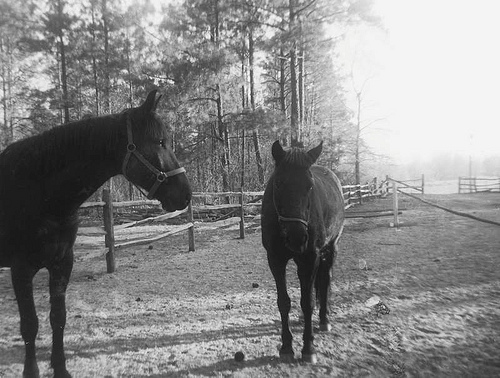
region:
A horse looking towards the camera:
[247, 135, 352, 366]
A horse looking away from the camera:
[0, 85, 190, 375]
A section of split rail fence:
[346, 172, 388, 241]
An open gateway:
[414, 170, 469, 199]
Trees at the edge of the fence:
[165, 31, 353, 143]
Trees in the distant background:
[378, 147, 498, 174]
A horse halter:
[116, 133, 186, 199]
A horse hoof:
[299, 348, 317, 365]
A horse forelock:
[281, 146, 311, 170]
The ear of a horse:
[308, 138, 327, 168]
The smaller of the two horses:
[247, 135, 347, 363]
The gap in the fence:
[419, 173, 463, 195]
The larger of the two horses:
[0, 84, 192, 376]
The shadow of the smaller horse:
[10, 303, 322, 377]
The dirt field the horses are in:
[2, 193, 499, 376]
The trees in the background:
[0, 1, 383, 227]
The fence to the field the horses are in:
[54, 170, 499, 276]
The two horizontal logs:
[390, 176, 499, 225]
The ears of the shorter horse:
[265, 133, 327, 165]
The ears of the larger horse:
[142, 86, 164, 114]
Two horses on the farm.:
[1, 111, 383, 316]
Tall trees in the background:
[148, 25, 299, 175]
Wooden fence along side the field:
[112, 194, 261, 247]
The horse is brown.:
[249, 141, 378, 362]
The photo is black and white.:
[45, 43, 499, 305]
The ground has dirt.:
[118, 284, 248, 366]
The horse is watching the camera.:
[263, 141, 355, 338]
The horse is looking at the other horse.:
[16, 94, 192, 335]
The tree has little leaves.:
[186, 13, 312, 157]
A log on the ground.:
[405, 204, 499, 234]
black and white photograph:
[37, 43, 469, 352]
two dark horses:
[20, 102, 387, 359]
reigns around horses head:
[117, 110, 204, 202]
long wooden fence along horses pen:
[98, 173, 295, 268]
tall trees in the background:
[187, 1, 309, 209]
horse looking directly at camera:
[274, 118, 345, 358]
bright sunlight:
[394, 18, 479, 158]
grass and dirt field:
[144, 246, 259, 358]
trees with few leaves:
[200, 0, 277, 196]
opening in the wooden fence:
[385, 166, 476, 200]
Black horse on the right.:
[246, 129, 353, 372]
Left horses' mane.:
[2, 98, 173, 175]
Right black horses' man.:
[275, 142, 314, 169]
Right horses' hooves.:
[272, 295, 335, 367]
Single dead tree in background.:
[343, 55, 370, 198]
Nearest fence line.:
[63, 179, 408, 270]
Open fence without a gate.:
[376, 172, 498, 194]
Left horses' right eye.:
[150, 129, 172, 157]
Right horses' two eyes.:
[271, 172, 321, 202]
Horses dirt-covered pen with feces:
[11, 200, 498, 375]